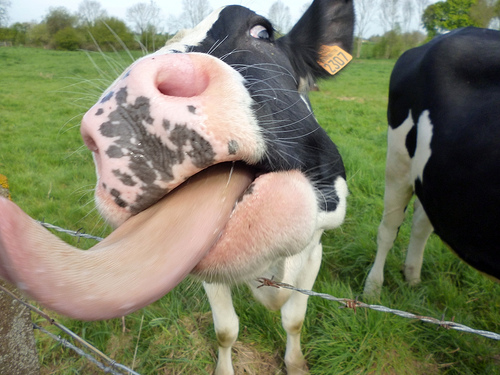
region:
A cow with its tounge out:
[5, 0, 382, 374]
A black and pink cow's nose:
[75, 61, 256, 205]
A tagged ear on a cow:
[279, 0, 376, 85]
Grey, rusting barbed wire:
[322, 288, 496, 358]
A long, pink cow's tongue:
[0, 175, 291, 326]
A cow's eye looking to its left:
[233, 18, 285, 50]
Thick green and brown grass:
[333, 323, 418, 373]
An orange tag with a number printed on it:
[316, 40, 353, 79]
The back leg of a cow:
[362, 135, 423, 312]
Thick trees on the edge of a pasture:
[12, 5, 138, 58]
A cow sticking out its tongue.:
[0, 0, 391, 372]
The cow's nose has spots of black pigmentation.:
[80, 54, 246, 207]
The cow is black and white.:
[90, 0, 365, 310]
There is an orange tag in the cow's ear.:
[311, 41, 351, 73]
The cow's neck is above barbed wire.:
[60, 212, 362, 317]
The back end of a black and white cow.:
[365, 26, 495, 299]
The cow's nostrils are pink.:
[80, 60, 226, 180]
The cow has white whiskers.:
[70, 15, 315, 162]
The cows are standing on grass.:
[201, 304, 436, 374]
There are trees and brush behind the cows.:
[0, 1, 495, 52]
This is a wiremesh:
[7, 203, 499, 356]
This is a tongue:
[2, 148, 248, 350]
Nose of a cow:
[59, 53, 238, 188]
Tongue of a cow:
[4, 199, 253, 340]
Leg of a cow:
[272, 270, 332, 373]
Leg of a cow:
[202, 273, 256, 373]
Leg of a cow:
[360, 122, 419, 319]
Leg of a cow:
[403, 187, 439, 322]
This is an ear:
[287, 0, 370, 87]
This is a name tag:
[296, 8, 364, 91]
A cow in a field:
[7, 3, 370, 374]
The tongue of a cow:
[0, 166, 274, 337]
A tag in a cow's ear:
[315, 41, 357, 80]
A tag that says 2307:
[316, 34, 355, 77]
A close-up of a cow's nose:
[67, 57, 245, 203]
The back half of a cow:
[357, 22, 498, 318]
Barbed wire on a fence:
[304, 279, 489, 354]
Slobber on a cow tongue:
[216, 154, 243, 205]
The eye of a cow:
[241, 14, 282, 55]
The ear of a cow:
[282, 3, 366, 83]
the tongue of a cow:
[1, 168, 248, 308]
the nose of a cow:
[140, 56, 225, 111]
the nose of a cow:
[76, 125, 129, 208]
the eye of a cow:
[241, 6, 284, 45]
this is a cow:
[356, 17, 498, 300]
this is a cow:
[6, 3, 367, 372]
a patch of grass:
[21, 76, 86, 168]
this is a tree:
[34, 5, 81, 65]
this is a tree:
[129, 0, 161, 57]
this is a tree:
[372, 0, 417, 67]